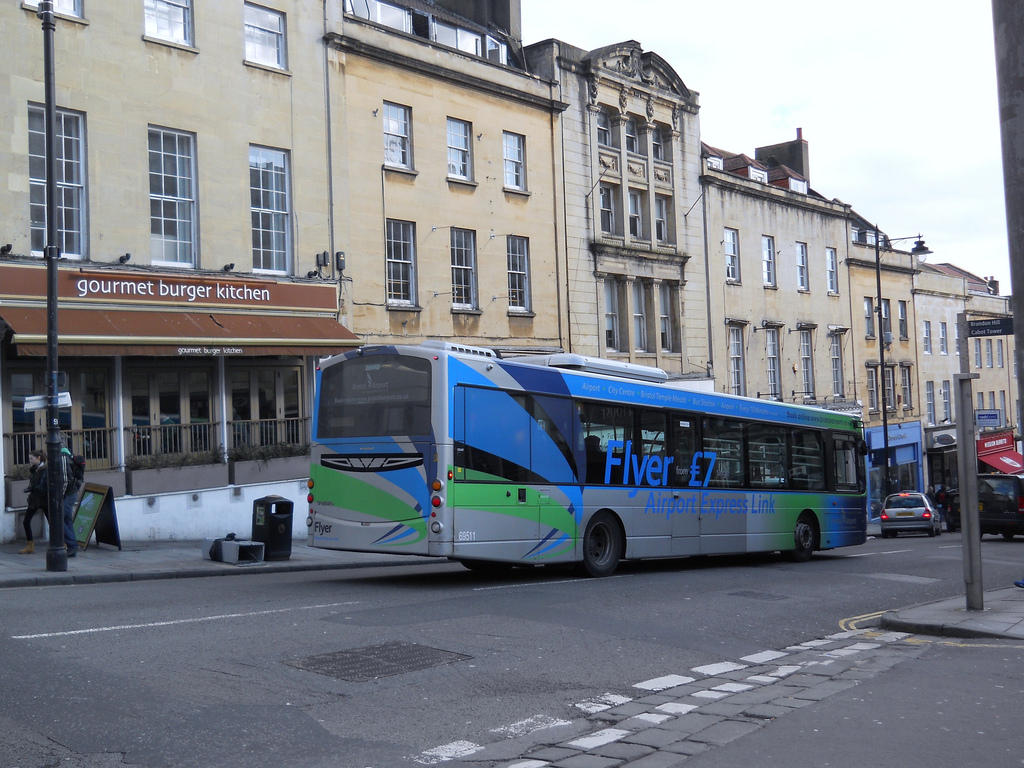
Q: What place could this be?
A: It is a street.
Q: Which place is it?
A: It is a street.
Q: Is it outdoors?
A: Yes, it is outdoors.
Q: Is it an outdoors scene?
A: Yes, it is outdoors.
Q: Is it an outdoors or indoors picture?
A: It is outdoors.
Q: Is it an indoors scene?
A: No, it is outdoors.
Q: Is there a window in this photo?
A: Yes, there is a window.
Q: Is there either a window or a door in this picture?
A: Yes, there is a window.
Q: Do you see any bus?
A: Yes, there is a bus.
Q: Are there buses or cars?
A: Yes, there is a bus.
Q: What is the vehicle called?
A: The vehicle is a bus.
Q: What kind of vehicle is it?
A: The vehicle is a bus.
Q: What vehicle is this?
A: This is a bus.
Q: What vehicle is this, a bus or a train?
A: This is a bus.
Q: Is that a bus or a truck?
A: That is a bus.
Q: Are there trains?
A: No, there are no trains.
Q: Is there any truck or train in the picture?
A: No, there are no trains or trucks.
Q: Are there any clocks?
A: No, there are no clocks.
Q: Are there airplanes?
A: No, there are no airplanes.